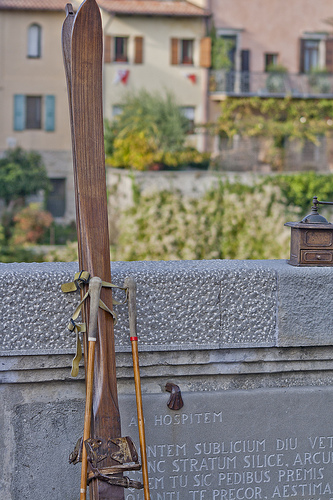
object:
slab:
[3, 261, 331, 498]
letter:
[213, 408, 224, 426]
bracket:
[162, 382, 184, 412]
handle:
[125, 280, 150, 499]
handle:
[75, 276, 101, 499]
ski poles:
[122, 284, 149, 500]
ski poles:
[75, 272, 101, 500]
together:
[57, 0, 124, 494]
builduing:
[205, 5, 329, 264]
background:
[1, 1, 329, 267]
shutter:
[45, 95, 57, 134]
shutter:
[12, 93, 27, 130]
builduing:
[2, 5, 211, 260]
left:
[0, 6, 212, 270]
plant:
[207, 96, 333, 148]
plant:
[280, 171, 332, 217]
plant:
[0, 137, 55, 198]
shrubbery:
[114, 181, 285, 260]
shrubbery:
[104, 94, 208, 167]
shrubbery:
[12, 202, 52, 242]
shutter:
[200, 34, 212, 69]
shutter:
[169, 38, 179, 65]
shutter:
[134, 35, 144, 65]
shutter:
[104, 34, 112, 62]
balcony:
[210, 71, 332, 100]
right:
[205, 0, 332, 291]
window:
[112, 34, 129, 63]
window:
[180, 39, 195, 65]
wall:
[111, 166, 289, 260]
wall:
[108, 17, 209, 169]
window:
[24, 94, 42, 132]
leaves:
[131, 180, 142, 202]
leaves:
[160, 82, 174, 102]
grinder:
[286, 196, 332, 266]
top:
[2, 261, 330, 301]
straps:
[78, 432, 145, 491]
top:
[72, 0, 103, 49]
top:
[63, 2, 75, 54]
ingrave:
[133, 417, 333, 500]